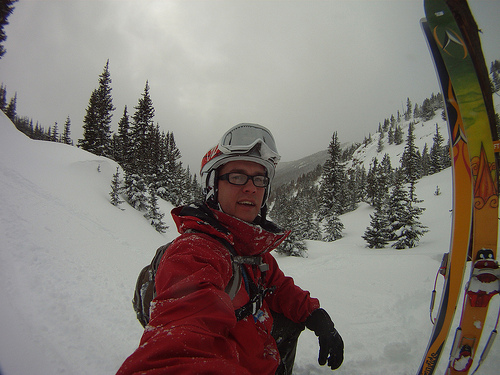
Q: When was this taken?
A: During the day.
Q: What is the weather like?
A: Snowy and cold.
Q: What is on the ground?
A: Snow.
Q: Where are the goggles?
A: On their forehead.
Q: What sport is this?
A: Skiing.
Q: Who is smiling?
A: The person in red coat.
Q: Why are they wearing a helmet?
A: Safety.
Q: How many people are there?
A: One.